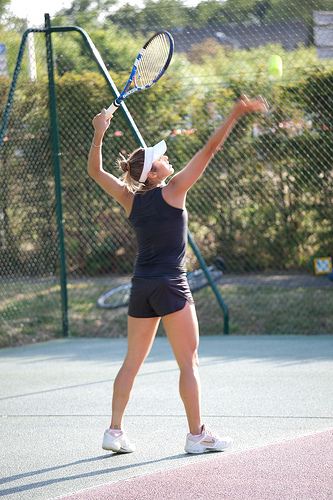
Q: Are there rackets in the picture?
A: Yes, there is a racket.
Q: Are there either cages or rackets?
A: Yes, there is a racket.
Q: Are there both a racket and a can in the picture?
A: No, there is a racket but no cans.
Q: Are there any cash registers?
A: No, there are no cash registers.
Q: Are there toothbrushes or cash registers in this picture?
A: No, there are no cash registers or toothbrushes.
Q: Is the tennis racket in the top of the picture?
A: Yes, the tennis racket is in the top of the image.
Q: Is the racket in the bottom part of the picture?
A: No, the racket is in the top of the image.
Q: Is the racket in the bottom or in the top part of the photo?
A: The racket is in the top of the image.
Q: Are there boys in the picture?
A: No, there are no boys.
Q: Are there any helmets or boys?
A: No, there are no boys or helmets.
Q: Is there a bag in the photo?
A: No, there are no bags.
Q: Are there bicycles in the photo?
A: Yes, there is a bicycle.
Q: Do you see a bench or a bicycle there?
A: Yes, there is a bicycle.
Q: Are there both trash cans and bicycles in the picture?
A: No, there is a bicycle but no trash cans.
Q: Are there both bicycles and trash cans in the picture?
A: No, there is a bicycle but no trash cans.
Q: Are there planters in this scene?
A: No, there are no planters.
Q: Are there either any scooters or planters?
A: No, there are no planters or scooters.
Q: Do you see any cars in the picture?
A: No, there are no cars.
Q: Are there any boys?
A: No, there are no boys.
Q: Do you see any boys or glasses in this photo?
A: No, there are no boys or glasses.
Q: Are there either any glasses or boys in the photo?
A: No, there are no boys or glasses.